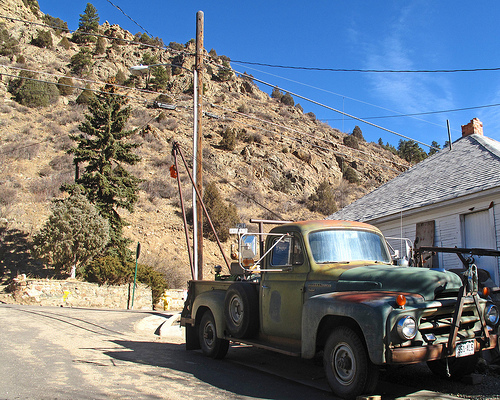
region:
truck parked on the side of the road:
[157, 184, 497, 396]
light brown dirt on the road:
[1, 310, 226, 399]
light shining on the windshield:
[316, 235, 365, 260]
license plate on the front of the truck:
[451, 336, 479, 360]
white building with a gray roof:
[304, 106, 499, 282]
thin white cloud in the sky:
[332, 6, 452, 128]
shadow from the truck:
[103, 343, 356, 399]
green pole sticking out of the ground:
[122, 242, 142, 313]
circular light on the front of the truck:
[392, 313, 418, 340]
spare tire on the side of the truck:
[215, 283, 261, 335]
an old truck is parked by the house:
[166, 133, 497, 392]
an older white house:
[349, 110, 494, 300]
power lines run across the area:
[25, 34, 482, 141]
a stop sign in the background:
[123, 238, 147, 311]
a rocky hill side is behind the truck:
[20, 12, 380, 232]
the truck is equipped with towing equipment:
[162, 133, 268, 280]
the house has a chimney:
[455, 110, 484, 142]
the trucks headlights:
[386, 300, 497, 338]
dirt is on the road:
[25, 309, 238, 396]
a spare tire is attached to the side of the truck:
[216, 273, 259, 342]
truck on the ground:
[171, 203, 476, 396]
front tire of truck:
[322, 334, 379, 390]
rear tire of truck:
[185, 310, 222, 347]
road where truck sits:
[3, 316, 170, 384]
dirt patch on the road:
[73, 337, 104, 351]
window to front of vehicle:
[308, 235, 388, 257]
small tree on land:
[47, 188, 113, 279]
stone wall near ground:
[29, 281, 151, 303]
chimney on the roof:
[455, 116, 487, 136]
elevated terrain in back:
[6, 7, 381, 262]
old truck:
[157, 209, 463, 390]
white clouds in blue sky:
[222, 3, 253, 21]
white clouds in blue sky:
[257, 19, 303, 54]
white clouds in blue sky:
[334, 10, 406, 49]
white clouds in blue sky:
[412, 25, 452, 54]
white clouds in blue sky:
[311, 3, 354, 39]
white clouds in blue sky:
[364, 43, 442, 88]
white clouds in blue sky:
[282, 42, 341, 83]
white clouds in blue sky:
[227, 8, 295, 51]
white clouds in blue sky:
[335, 24, 400, 76]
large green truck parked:
[165, 199, 486, 396]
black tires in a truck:
[314, 309, 371, 390]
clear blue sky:
[204, 4, 493, 119]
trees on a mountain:
[10, 6, 329, 216]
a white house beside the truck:
[348, 117, 497, 231]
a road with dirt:
[1, 305, 163, 397]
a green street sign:
[118, 217, 149, 324]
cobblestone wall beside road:
[19, 277, 154, 312]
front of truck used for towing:
[421, 237, 497, 351]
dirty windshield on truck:
[303, 224, 400, 265]